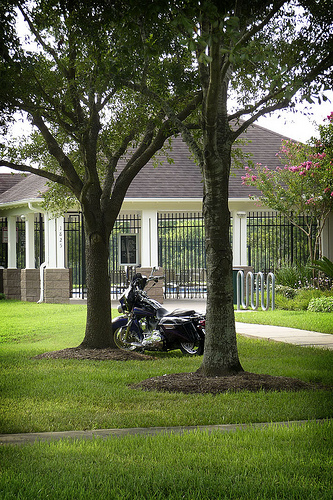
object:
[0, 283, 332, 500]
grass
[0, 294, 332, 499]
ground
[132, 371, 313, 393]
mound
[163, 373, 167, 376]
paper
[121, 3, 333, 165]
tree trunk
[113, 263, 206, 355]
motorcycle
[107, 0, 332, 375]
tree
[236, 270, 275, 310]
railing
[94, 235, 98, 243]
cross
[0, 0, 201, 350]
tree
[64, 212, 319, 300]
bars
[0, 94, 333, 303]
building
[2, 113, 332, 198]
shingles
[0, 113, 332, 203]
roof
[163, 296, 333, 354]
concrete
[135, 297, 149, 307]
motor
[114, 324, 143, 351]
tires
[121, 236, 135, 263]
plaque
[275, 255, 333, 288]
plants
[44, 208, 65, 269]
beam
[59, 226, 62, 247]
numbers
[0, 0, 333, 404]
trees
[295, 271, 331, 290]
flowers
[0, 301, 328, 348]
sun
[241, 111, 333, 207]
flowers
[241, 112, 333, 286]
tree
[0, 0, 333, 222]
leaves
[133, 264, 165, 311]
handlebars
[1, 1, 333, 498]
photo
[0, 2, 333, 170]
daytime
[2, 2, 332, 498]
outdoors